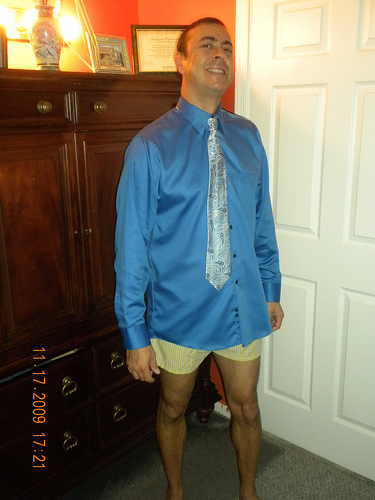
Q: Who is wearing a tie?
A: The man.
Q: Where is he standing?
A: In front of the dresser.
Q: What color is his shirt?
A: Blue.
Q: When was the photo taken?
A: 11 17 2009.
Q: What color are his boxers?
A: Yellow.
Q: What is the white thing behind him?
A: A door.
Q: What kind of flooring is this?
A: Carpet.